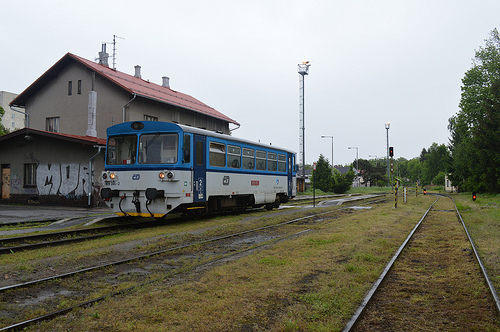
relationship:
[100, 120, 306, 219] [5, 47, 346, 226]
train at station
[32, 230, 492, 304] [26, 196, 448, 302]
train tracks in foreground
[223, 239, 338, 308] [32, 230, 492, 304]
grass between train tracks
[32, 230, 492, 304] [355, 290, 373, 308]
train tracks look wet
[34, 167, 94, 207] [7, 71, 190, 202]
graffiti on building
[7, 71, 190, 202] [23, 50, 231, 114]
building has roof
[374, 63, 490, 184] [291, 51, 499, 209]
trees in background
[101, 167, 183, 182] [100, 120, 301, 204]
headlights on train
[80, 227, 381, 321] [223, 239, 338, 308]
tracks covered in grass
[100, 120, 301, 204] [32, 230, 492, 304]
train sitting on train tracks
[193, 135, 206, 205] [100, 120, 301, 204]
door of train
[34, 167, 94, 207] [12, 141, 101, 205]
graffiti on wall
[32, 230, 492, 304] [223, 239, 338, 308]
train tracks in grass